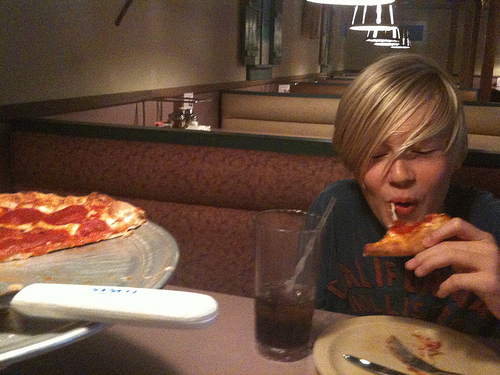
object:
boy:
[294, 50, 500, 340]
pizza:
[361, 201, 450, 259]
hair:
[329, 52, 470, 193]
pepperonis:
[70, 218, 112, 247]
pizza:
[0, 190, 149, 264]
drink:
[250, 281, 321, 350]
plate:
[311, 313, 500, 375]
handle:
[6, 280, 224, 331]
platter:
[0, 217, 183, 375]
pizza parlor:
[0, 0, 499, 375]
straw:
[283, 196, 336, 294]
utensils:
[342, 350, 408, 375]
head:
[330, 52, 472, 231]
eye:
[409, 147, 442, 156]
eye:
[366, 149, 388, 162]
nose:
[384, 153, 415, 188]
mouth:
[384, 195, 422, 218]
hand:
[400, 214, 500, 322]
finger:
[434, 271, 474, 298]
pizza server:
[1, 279, 227, 332]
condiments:
[181, 90, 195, 99]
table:
[0, 283, 360, 375]